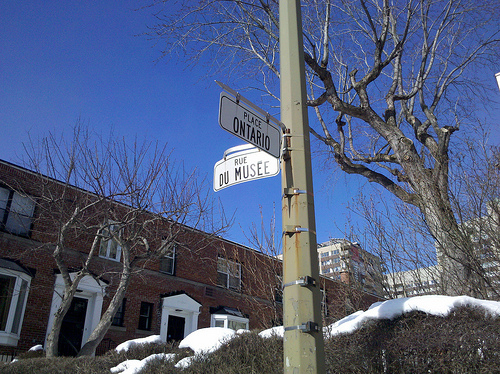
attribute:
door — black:
[44, 265, 119, 357]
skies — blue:
[1, 0, 498, 270]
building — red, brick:
[5, 124, 285, 365]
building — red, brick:
[4, 160, 391, 372]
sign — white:
[213, 89, 287, 159]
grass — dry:
[0, 303, 499, 371]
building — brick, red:
[29, 162, 274, 340]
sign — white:
[188, 99, 302, 197]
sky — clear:
[0, 0, 498, 274]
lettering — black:
[231, 115, 271, 147]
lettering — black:
[219, 162, 264, 187]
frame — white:
[79, 291, 102, 358]